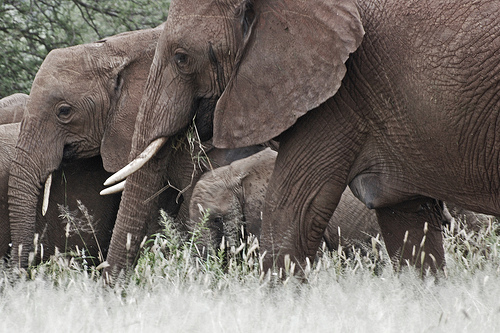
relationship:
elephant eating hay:
[92, 0, 499, 283] [61, 224, 421, 319]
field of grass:
[0, 205, 500, 332] [4, 200, 496, 330]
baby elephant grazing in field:
[189, 147, 494, 275] [20, 72, 475, 310]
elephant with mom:
[8, 25, 281, 283] [149, 7, 499, 208]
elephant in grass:
[92, 0, 499, 283] [4, 200, 496, 330]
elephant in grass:
[12, 25, 166, 266] [4, 200, 496, 330]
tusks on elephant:
[101, 136, 167, 186] [92, 0, 499, 283]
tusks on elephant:
[100, 180, 126, 197] [92, 0, 499, 283]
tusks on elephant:
[39, 167, 54, 217] [92, 0, 499, 283]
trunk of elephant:
[4, 120, 63, 277] [12, 25, 166, 266]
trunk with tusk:
[4, 120, 63, 277] [40, 169, 57, 214]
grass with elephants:
[157, 205, 222, 284] [0, 1, 497, 286]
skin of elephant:
[393, 35, 483, 157] [93, 0, 498, 332]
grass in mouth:
[148, 117, 225, 186] [123, 87, 238, 174]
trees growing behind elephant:
[0, 2, 172, 99] [92, 0, 499, 283]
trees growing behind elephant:
[0, 2, 172, 99] [12, 25, 166, 266]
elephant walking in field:
[92, 0, 499, 283] [0, 205, 500, 332]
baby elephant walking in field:
[189, 147, 494, 275] [0, 205, 500, 332]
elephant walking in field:
[8, 25, 281, 283] [0, 205, 500, 332]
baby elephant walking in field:
[189, 143, 385, 260] [0, 205, 500, 332]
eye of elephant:
[159, 32, 205, 88] [92, 0, 499, 283]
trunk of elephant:
[7, 120, 64, 277] [7, 23, 195, 268]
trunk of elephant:
[96, 70, 193, 286] [146, 29, 325, 146]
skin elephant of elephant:
[381, 13, 493, 198] [92, 0, 499, 283]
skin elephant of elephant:
[288, 138, 322, 240] [92, 0, 499, 283]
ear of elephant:
[238, 13, 323, 108] [175, 12, 496, 204]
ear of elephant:
[97, 35, 161, 175] [29, 46, 186, 218]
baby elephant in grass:
[189, 143, 385, 260] [145, 257, 261, 332]